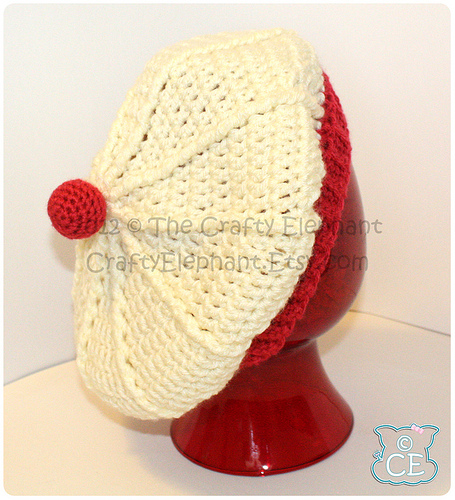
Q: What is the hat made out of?
A: Yarn.